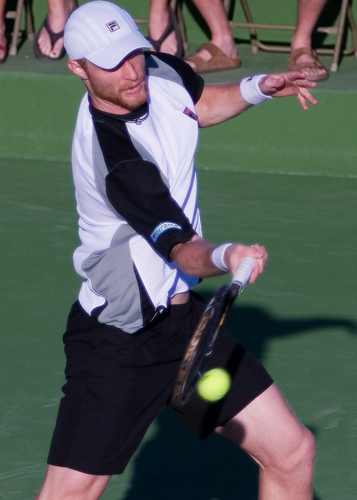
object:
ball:
[195, 366, 232, 403]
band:
[240, 74, 273, 106]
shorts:
[46, 289, 275, 475]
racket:
[171, 257, 256, 409]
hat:
[63, 0, 153, 70]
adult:
[35, 1, 318, 500]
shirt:
[70, 51, 205, 334]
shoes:
[182, 40, 242, 73]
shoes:
[34, 14, 66, 62]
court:
[2, 50, 356, 497]